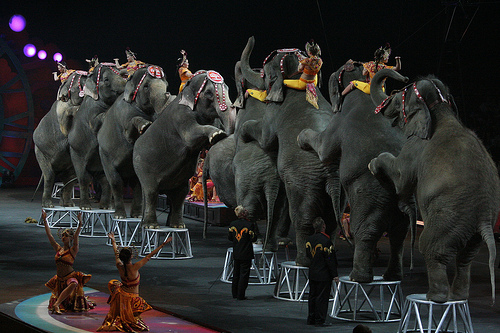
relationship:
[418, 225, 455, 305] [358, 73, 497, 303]
leg of an elephant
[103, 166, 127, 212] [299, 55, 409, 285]
leg of an elephant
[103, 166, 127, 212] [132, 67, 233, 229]
leg of an elephant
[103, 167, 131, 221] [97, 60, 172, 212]
leg of an elephant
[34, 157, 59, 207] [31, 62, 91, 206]
leg of an elephant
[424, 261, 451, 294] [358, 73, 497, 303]
leg of an elephant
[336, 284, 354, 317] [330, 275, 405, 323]
beams support structure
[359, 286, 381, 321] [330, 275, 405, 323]
beams support structure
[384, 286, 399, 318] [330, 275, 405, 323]
beams support structure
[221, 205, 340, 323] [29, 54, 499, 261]
male performers monitoring elephants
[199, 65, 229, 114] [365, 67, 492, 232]
headdress on elephant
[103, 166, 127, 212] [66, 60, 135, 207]
leg of elephant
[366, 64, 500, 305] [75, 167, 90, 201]
elephant has leg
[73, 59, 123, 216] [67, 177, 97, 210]
elephant has leg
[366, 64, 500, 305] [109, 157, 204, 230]
elephant has leg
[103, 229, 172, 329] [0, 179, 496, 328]
female performer on floor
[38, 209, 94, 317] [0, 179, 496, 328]
female performer on floor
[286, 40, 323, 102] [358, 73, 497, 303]
woman on elephant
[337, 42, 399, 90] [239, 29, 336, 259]
woman on elephant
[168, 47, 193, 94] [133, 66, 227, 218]
woman on elephant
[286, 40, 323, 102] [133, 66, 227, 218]
woman on elephant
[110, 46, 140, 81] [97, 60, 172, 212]
woman on elephant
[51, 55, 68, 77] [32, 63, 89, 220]
woman on elephant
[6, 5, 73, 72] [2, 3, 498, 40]
purple lights on ceiling